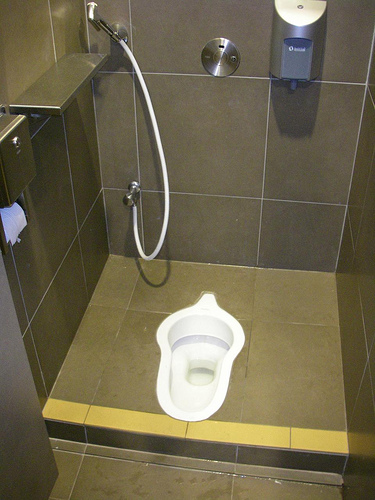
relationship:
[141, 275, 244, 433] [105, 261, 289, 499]
toilet on ground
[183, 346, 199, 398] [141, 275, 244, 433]
waiter in toilet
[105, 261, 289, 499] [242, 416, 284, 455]
floor has yellow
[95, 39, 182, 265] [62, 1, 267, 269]
hose on wall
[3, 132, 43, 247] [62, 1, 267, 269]
toilet paper on wall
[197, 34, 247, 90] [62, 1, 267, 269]
flush button on wall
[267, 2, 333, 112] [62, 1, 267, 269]
hand sanitizer on wall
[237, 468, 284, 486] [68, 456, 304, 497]
grout on floor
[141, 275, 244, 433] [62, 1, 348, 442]
toilet in stall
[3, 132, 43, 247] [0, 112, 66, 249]
toilet paper in dispenser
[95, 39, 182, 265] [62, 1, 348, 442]
hose for shower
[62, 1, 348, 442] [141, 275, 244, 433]
stall for toilet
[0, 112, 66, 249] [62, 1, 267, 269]
dispenser on wall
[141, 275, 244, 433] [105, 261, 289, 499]
toilet seat on ground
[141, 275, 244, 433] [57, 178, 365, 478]
toilet in bathroom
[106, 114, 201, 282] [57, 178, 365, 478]
shower cord for bathroom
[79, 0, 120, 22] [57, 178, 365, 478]
shower head in bathroom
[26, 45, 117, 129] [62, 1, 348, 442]
shelf in shower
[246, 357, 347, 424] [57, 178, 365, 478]
tile in bathroom